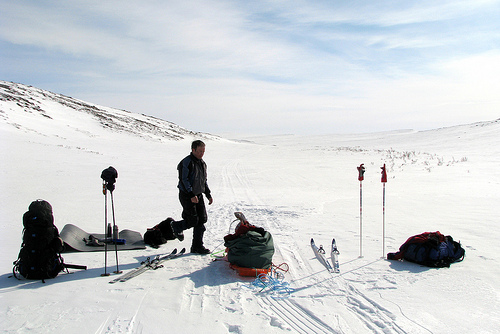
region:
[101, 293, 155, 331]
ski track in snow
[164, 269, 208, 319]
ski track in snow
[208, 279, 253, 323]
ski track in snow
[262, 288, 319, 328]
ski track in snow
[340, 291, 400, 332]
ski track in snow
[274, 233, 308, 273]
ski track in snow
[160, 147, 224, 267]
skier in white snow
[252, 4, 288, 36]
white clouds in blue sky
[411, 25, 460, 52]
white clouds in blue sky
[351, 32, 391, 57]
white clouds in blue sky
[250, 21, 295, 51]
white clouds in blue sky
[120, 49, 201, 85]
white clouds in blue sky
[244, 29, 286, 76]
white clouds in blue sky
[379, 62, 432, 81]
white clouds in blue sky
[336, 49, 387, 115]
white clouds in blue sky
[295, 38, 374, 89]
white clouds in blue sky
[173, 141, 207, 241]
skier in black outfit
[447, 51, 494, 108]
white clouds in blue sky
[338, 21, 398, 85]
white clouds in blue sky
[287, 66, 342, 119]
white clouds in blue sky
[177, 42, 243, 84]
white clouds in blue sky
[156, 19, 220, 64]
white clouds in blue sky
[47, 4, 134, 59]
white clouds in blue sky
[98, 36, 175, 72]
white clouds in blue sky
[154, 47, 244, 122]
white clouds in blue sky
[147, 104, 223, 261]
man walks on snow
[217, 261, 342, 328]
tracks in white snow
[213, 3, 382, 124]
blue and white sky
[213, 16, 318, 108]
thin clouds in sky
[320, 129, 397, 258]
two poles in snow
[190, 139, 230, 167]
man has dark hair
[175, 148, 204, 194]
man has black coat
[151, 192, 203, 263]
man has dark pants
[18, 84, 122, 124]
brown ground on hill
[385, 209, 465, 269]
bag lying on snow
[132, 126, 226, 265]
this is a man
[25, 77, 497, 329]
snow on the ground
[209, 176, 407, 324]
tracks in the snow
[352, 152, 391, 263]
a set of ski poles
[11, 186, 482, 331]
bags on the snow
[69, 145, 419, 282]
ski poles stuck in snow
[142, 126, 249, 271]
the man is walking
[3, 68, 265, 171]
elevated land in background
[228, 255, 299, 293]
blue rope on ground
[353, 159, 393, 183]
red handles on ski poles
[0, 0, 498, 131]
A blue cloudy sky.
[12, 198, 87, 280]
Largest black pack sitting in the snow.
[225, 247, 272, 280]
Orange plastic sled.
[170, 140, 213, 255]
Dark haired man walking.